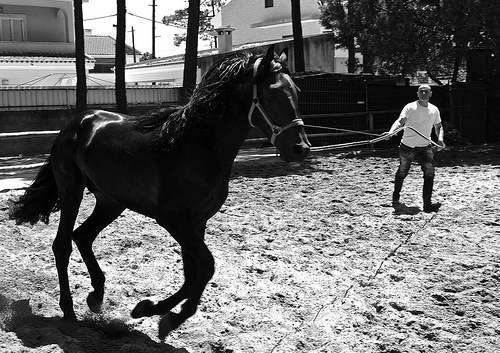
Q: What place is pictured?
A: It is a field.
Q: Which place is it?
A: It is a field.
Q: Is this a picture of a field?
A: Yes, it is showing a field.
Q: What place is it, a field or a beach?
A: It is a field.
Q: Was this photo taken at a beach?
A: No, the picture was taken in a field.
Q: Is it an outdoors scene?
A: Yes, it is outdoors.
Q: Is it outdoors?
A: Yes, it is outdoors.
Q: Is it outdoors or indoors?
A: It is outdoors.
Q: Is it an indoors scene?
A: No, it is outdoors.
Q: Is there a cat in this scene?
A: No, there are no cats.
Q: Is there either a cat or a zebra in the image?
A: No, there are no cats or zebras.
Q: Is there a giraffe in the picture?
A: No, there are no giraffes.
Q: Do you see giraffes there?
A: No, there are no giraffes.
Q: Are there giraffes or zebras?
A: No, there are no giraffes or zebras.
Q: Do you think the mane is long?
A: Yes, the mane is long.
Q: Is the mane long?
A: Yes, the mane is long.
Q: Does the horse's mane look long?
A: Yes, the mane is long.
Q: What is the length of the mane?
A: The mane is long.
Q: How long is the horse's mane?
A: The mane is long.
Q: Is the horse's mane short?
A: No, the mane is long.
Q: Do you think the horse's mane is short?
A: No, the mane is long.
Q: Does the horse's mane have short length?
A: No, the mane is long.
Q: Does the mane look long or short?
A: The mane is long.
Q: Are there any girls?
A: No, there are no girls.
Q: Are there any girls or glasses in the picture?
A: No, there are no girls or glasses.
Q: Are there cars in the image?
A: No, there are no cars.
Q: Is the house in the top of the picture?
A: Yes, the house is in the top of the image.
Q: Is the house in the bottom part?
A: No, the house is in the top of the image.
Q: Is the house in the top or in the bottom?
A: The house is in the top of the image.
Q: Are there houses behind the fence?
A: Yes, there is a house behind the fence.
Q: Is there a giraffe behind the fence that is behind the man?
A: No, there is a house behind the fence.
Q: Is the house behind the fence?
A: Yes, the house is behind the fence.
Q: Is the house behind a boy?
A: No, the house is behind the fence.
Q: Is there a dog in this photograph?
A: No, there are no dogs.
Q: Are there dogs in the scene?
A: No, there are no dogs.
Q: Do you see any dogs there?
A: No, there are no dogs.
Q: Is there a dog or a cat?
A: No, there are no dogs or cats.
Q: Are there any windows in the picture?
A: Yes, there is a window.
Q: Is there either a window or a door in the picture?
A: Yes, there is a window.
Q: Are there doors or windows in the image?
A: Yes, there is a window.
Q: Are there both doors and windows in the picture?
A: No, there is a window but no doors.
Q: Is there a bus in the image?
A: No, there are no buses.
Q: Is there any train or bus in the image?
A: No, there are no buses or trains.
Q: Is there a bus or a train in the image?
A: No, there are no buses or trains.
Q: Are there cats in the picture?
A: No, there are no cats.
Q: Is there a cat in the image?
A: No, there are no cats.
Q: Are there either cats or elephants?
A: No, there are no cats or elephants.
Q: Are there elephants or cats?
A: No, there are no cats or elephants.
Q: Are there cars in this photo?
A: No, there are no cars.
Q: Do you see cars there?
A: No, there are no cars.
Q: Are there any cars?
A: No, there are no cars.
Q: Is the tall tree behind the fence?
A: Yes, the tree is behind the fence.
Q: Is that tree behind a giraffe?
A: No, the tree is behind the fence.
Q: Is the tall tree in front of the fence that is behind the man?
A: No, the tree is behind the fence.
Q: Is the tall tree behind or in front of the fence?
A: The tree is behind the fence.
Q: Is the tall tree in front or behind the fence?
A: The tree is behind the fence.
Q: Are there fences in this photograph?
A: Yes, there is a fence.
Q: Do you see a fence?
A: Yes, there is a fence.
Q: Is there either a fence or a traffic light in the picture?
A: Yes, there is a fence.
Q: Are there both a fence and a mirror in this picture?
A: No, there is a fence but no mirrors.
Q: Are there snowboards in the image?
A: No, there are no snowboards.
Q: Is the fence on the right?
A: Yes, the fence is on the right of the image.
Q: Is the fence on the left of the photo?
A: No, the fence is on the right of the image.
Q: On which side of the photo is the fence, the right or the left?
A: The fence is on the right of the image.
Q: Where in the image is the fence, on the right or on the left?
A: The fence is on the right of the image.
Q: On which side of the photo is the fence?
A: The fence is on the right of the image.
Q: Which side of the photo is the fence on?
A: The fence is on the right of the image.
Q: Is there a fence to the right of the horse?
A: Yes, there is a fence to the right of the horse.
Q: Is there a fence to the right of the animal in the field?
A: Yes, there is a fence to the right of the horse.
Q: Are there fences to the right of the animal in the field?
A: Yes, there is a fence to the right of the horse.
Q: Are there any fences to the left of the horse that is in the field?
A: No, the fence is to the right of the horse.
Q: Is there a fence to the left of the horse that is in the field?
A: No, the fence is to the right of the horse.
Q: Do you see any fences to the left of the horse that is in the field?
A: No, the fence is to the right of the horse.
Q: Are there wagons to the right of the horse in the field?
A: No, there is a fence to the right of the horse.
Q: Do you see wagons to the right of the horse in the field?
A: No, there is a fence to the right of the horse.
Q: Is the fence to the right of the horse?
A: Yes, the fence is to the right of the horse.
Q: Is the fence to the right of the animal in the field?
A: Yes, the fence is to the right of the horse.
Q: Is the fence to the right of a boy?
A: No, the fence is to the right of the horse.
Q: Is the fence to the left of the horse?
A: No, the fence is to the right of the horse.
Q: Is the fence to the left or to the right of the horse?
A: The fence is to the right of the horse.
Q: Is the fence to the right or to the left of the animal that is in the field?
A: The fence is to the right of the horse.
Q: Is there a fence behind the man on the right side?
A: Yes, there is a fence behind the man.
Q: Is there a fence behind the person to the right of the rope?
A: Yes, there is a fence behind the man.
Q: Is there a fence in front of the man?
A: No, the fence is behind the man.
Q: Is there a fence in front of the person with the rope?
A: No, the fence is behind the man.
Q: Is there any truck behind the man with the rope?
A: No, there is a fence behind the man.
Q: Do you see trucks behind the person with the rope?
A: No, there is a fence behind the man.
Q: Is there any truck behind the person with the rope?
A: No, there is a fence behind the man.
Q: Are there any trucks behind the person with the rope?
A: No, there is a fence behind the man.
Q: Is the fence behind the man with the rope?
A: Yes, the fence is behind the man.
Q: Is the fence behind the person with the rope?
A: Yes, the fence is behind the man.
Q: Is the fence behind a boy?
A: No, the fence is behind the man.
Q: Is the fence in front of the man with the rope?
A: No, the fence is behind the man.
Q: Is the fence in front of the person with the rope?
A: No, the fence is behind the man.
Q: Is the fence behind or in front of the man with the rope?
A: The fence is behind the man.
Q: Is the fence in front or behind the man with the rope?
A: The fence is behind the man.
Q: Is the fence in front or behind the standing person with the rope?
A: The fence is behind the man.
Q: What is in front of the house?
A: The fence is in front of the house.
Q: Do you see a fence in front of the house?
A: Yes, there is a fence in front of the house.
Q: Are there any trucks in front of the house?
A: No, there is a fence in front of the house.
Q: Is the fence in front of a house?
A: Yes, the fence is in front of a house.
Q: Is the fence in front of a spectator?
A: No, the fence is in front of a house.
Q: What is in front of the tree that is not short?
A: The fence is in front of the tree.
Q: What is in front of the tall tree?
A: The fence is in front of the tree.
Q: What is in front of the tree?
A: The fence is in front of the tree.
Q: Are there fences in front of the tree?
A: Yes, there is a fence in front of the tree.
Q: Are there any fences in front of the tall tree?
A: Yes, there is a fence in front of the tree.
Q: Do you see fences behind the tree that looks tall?
A: No, the fence is in front of the tree.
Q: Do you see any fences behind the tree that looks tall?
A: No, the fence is in front of the tree.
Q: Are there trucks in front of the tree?
A: No, there is a fence in front of the tree.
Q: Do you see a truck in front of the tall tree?
A: No, there is a fence in front of the tree.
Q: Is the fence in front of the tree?
A: Yes, the fence is in front of the tree.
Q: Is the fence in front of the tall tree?
A: Yes, the fence is in front of the tree.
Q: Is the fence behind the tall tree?
A: No, the fence is in front of the tree.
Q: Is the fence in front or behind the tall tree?
A: The fence is in front of the tree.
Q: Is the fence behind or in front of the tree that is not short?
A: The fence is in front of the tree.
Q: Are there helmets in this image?
A: No, there are no helmets.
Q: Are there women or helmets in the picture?
A: No, there are no helmets or women.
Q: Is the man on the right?
A: Yes, the man is on the right of the image.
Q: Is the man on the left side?
A: No, the man is on the right of the image.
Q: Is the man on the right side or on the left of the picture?
A: The man is on the right of the image.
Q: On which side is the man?
A: The man is on the right of the image.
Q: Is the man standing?
A: Yes, the man is standing.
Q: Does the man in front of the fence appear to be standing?
A: Yes, the man is standing.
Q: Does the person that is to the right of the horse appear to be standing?
A: Yes, the man is standing.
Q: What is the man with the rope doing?
A: The man is standing.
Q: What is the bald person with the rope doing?
A: The man is standing.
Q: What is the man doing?
A: The man is standing.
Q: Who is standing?
A: The man is standing.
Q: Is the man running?
A: No, the man is standing.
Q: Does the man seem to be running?
A: No, the man is standing.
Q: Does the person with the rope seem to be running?
A: No, the man is standing.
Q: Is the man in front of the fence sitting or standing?
A: The man is standing.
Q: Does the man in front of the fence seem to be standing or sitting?
A: The man is standing.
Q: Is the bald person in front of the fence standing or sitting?
A: The man is standing.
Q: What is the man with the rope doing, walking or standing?
A: The man is standing.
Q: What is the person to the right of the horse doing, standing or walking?
A: The man is standing.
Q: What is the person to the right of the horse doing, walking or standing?
A: The man is standing.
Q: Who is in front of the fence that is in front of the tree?
A: The man is in front of the fence.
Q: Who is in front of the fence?
A: The man is in front of the fence.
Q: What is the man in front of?
A: The man is in front of the fence.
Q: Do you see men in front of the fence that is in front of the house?
A: Yes, there is a man in front of the fence.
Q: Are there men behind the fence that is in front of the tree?
A: No, the man is in front of the fence.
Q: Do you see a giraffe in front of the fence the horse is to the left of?
A: No, there is a man in front of the fence.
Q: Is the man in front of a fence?
A: Yes, the man is in front of a fence.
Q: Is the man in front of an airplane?
A: No, the man is in front of a fence.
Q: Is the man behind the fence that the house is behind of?
A: No, the man is in front of the fence.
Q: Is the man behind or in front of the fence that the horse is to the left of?
A: The man is in front of the fence.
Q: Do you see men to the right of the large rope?
A: Yes, there is a man to the right of the rope.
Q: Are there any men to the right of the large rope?
A: Yes, there is a man to the right of the rope.